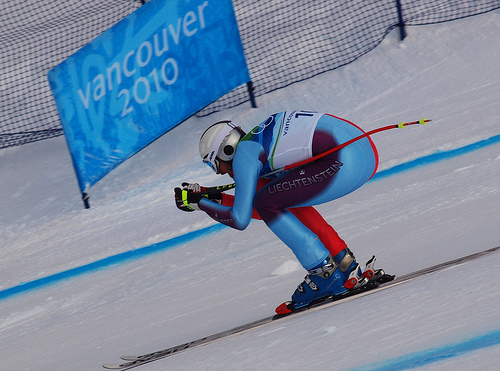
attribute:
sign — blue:
[30, 16, 264, 114]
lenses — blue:
[204, 156, 217, 171]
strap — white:
[220, 134, 233, 146]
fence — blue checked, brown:
[275, 17, 323, 58]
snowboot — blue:
[273, 267, 354, 309]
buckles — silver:
[312, 267, 342, 279]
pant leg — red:
[314, 210, 346, 258]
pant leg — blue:
[271, 219, 307, 263]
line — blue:
[450, 122, 499, 166]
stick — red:
[368, 107, 393, 141]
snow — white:
[380, 66, 395, 85]